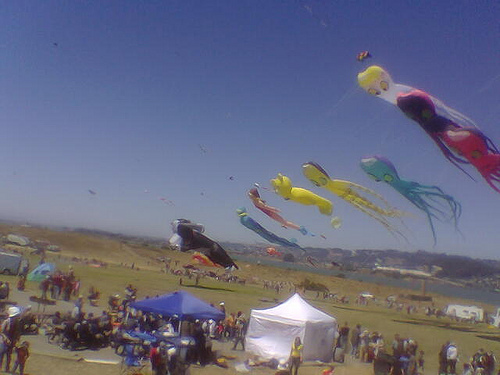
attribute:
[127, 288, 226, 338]
tent — blue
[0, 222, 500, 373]
ground — grassy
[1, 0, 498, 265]
sky — blue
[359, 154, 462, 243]
kite — blue, octupus shaped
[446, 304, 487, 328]
camper — white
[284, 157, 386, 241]
octopus — yellow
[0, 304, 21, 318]
hat — white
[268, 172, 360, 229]
kite — yellow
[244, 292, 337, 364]
tent — white, square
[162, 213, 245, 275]
dog — black and white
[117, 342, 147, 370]
chair — blue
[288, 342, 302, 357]
shirt — yellow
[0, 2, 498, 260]
blue sky — slightly misty, sunny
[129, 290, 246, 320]
tent — blue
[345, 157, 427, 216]
kite — blue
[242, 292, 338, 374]
tent — white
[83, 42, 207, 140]
skies — clear, blue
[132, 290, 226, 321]
tent — purple